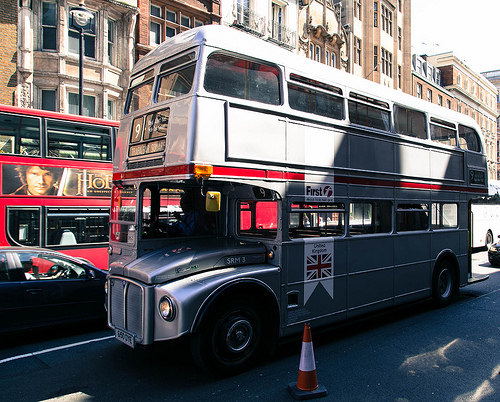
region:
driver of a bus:
[155, 188, 210, 242]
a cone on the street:
[281, 317, 347, 398]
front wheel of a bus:
[189, 274, 300, 395]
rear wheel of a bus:
[412, 253, 478, 310]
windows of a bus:
[240, 68, 472, 150]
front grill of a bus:
[109, 268, 149, 348]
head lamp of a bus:
[155, 284, 178, 316]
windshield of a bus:
[113, 152, 142, 239]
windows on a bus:
[283, 190, 475, 235]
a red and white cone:
[281, 302, 337, 394]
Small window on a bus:
[201, 47, 288, 124]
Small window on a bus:
[285, 63, 346, 137]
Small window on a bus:
[346, 79, 392, 144]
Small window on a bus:
[392, 98, 425, 148]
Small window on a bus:
[428, 106, 459, 155]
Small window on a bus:
[458, 117, 485, 158]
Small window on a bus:
[288, 191, 342, 248]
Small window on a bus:
[348, 195, 396, 243]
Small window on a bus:
[396, 196, 432, 244]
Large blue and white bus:
[108, 30, 486, 365]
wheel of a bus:
[192, 264, 279, 376]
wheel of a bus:
[430, 246, 464, 311]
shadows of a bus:
[151, 359, 227, 385]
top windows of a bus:
[227, 64, 493, 149]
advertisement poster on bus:
[4, 159, 119, 201]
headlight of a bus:
[152, 288, 182, 325]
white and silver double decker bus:
[129, 42, 475, 343]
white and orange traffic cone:
[294, 315, 331, 385]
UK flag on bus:
[286, 233, 348, 295]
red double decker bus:
[6, 88, 108, 270]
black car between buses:
[1, 260, 98, 337]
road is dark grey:
[323, 295, 476, 400]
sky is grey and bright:
[423, 12, 499, 47]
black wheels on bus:
[204, 287, 269, 377]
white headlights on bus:
[138, 303, 183, 339]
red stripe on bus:
[201, 150, 496, 217]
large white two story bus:
[98, 30, 487, 350]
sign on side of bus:
[295, 240, 331, 301]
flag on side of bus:
[304, 246, 336, 284]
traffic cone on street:
[295, 325, 318, 395]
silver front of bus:
[104, 284, 145, 331]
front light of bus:
[148, 297, 175, 321]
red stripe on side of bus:
[214, 165, 304, 178]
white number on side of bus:
[223, 253, 250, 263]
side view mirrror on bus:
[203, 186, 222, 211]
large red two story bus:
[17, 103, 97, 253]